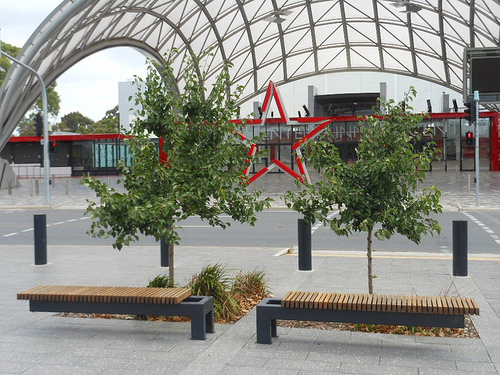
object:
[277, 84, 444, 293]
tree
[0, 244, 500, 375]
stone brick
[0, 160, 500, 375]
pavement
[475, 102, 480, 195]
silver pole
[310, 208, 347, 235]
white lines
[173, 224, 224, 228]
white lines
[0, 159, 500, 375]
street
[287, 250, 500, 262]
line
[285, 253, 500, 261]
curb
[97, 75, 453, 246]
leaves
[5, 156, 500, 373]
ground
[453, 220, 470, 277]
pole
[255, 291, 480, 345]
bed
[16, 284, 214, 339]
bed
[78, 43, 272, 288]
tree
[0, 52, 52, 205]
pole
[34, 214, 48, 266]
black poles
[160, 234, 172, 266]
pole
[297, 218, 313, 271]
pole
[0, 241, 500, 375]
sidewalk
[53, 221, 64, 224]
lines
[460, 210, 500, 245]
broken line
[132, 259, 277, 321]
grass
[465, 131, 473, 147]
traffic light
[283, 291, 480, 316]
slats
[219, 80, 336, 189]
star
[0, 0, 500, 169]
building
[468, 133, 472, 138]
light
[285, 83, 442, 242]
leaves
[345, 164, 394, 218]
leaves